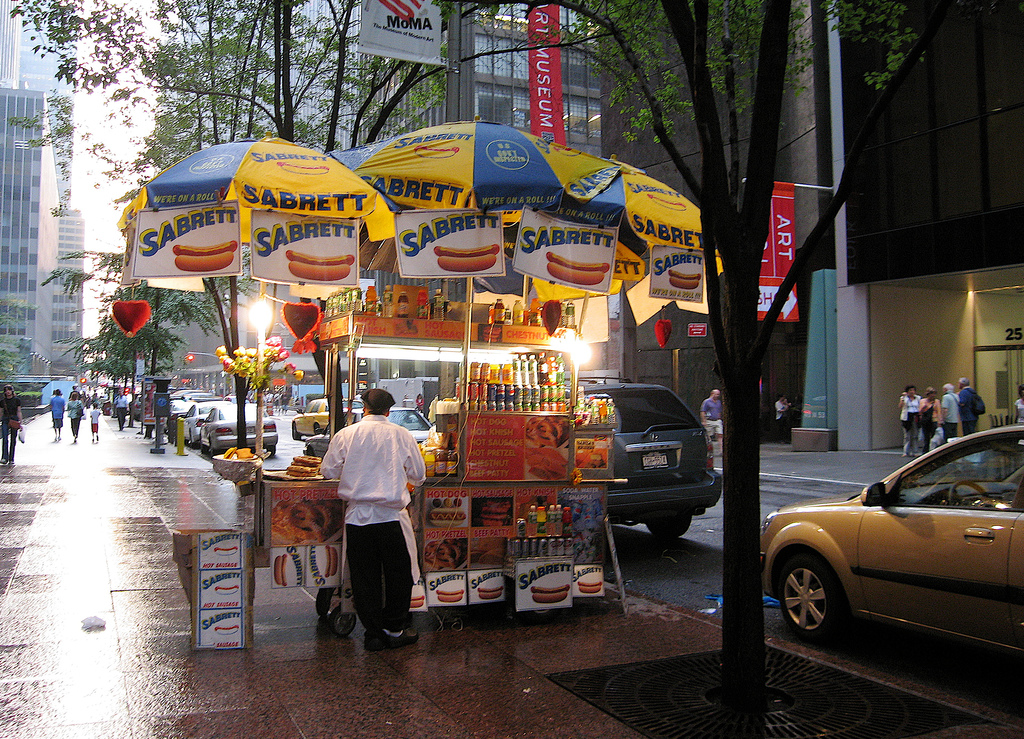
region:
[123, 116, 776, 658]
A blue and yellow hot dog stand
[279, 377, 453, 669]
Man wearing white apron working at stand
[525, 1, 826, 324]
Banners for the Modern Museum of Art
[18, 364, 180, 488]
People walking in the distance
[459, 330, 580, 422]
Many beverages available for purchase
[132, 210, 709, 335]
Banners for Sabrett hot dogs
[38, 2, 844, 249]
Trees with green leaves above stand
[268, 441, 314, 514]
Freshly prepared hot dogs on stand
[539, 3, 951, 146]
green leaves of tree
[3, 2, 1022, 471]
buildings along city street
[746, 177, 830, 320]
red and white banner on pole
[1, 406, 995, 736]
wet surface of sidewalk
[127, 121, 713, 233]
tops of three open umbrellas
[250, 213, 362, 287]
sign with picture of hotdog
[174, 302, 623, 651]
food cart on sidewalk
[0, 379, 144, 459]
people walking on sidewalk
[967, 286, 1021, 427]
number on glass wall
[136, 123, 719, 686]
Mobile hotdog stand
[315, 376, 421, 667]
Hotdog vendor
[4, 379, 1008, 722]
Rain covered sidewalk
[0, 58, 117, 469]
Multi-floored skyscraper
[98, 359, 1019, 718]
Cars parked inspots on a street.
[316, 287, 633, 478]
A collection of various drinks for sale.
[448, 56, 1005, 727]
A young tree planted on a city street.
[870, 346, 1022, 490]
A group of people gathered on a sidewalk..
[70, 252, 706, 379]
Heart shaped decorations.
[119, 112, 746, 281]
Umbrellas covered with advertising.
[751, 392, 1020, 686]
a car on a street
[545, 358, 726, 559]
a car on a street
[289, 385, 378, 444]
a car on a street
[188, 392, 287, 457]
a car on a street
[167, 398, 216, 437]
a car on a street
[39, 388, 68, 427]
a person walking on a sidewalk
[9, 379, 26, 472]
a person walking on a sidewalk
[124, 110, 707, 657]
man selling hot dogs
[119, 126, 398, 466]
blue and yellow umbrella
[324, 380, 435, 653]
man in a white apron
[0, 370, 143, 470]
people walking on a sidewalk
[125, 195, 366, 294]
two hot dog signs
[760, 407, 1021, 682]
small silver car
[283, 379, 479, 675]
Man in white shirt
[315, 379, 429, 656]
Man in black pants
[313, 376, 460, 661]
Man in black shoes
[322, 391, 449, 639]
Man wearing white apron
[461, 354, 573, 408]
Soda on the cart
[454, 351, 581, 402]
Cans on the cart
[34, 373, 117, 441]
People on the sidewalk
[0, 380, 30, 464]
Woman in black shirt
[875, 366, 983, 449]
People on the sidewalk